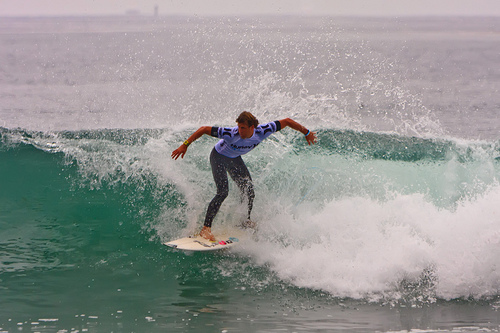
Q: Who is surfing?
A: A man.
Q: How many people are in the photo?
A: One.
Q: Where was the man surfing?
A: The ocean.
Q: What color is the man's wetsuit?
A: Purple and black.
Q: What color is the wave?
A: Aquamarine.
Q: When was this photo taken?
A: In the daytime.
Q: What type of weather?
A: Hazy.